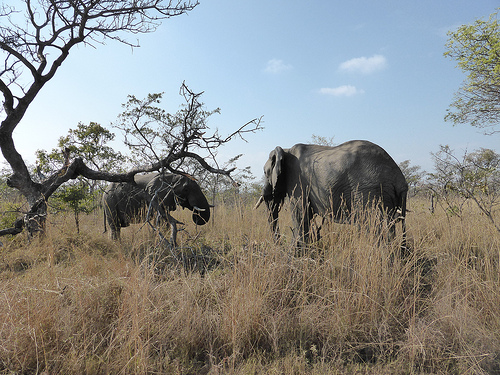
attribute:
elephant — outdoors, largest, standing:
[254, 140, 412, 259]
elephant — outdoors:
[101, 172, 217, 242]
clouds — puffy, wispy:
[0, 0, 500, 188]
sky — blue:
[1, 0, 500, 194]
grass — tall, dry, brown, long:
[0, 190, 500, 373]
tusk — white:
[255, 194, 263, 212]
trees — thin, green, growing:
[0, 0, 500, 232]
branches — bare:
[0, 0, 264, 234]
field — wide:
[1, 1, 500, 374]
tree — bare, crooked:
[1, 1, 265, 240]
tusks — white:
[193, 201, 217, 211]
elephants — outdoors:
[104, 139, 410, 259]